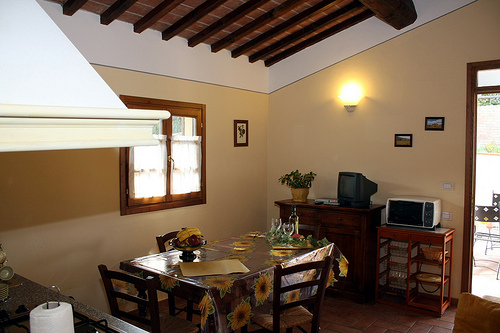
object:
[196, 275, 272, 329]
sunflowers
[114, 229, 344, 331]
table cloth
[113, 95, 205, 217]
window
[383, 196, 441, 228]
microwave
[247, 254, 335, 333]
chair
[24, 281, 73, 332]
towel roll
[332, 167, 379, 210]
tv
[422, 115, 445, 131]
picture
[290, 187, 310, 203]
vase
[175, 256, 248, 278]
mat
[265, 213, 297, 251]
glasses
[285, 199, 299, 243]
wine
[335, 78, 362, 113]
light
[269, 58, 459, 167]
wall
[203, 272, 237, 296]
sunflower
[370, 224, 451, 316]
stand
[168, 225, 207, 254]
fruit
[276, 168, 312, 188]
plant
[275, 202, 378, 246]
stand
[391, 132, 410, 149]
picture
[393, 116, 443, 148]
set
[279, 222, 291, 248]
glass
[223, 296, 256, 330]
daisy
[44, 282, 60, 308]
holder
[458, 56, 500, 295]
door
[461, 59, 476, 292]
wooden frame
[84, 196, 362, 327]
dining area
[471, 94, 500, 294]
patio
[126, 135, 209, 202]
covered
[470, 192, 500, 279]
chairs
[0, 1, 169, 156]
vent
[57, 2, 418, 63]
beams